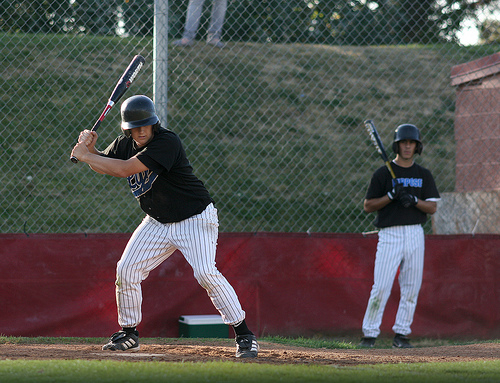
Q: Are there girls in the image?
A: No, there are no girls.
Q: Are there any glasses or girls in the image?
A: No, there are no girls or glasses.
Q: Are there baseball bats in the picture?
A: Yes, there is a baseball bat.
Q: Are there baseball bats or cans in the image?
A: Yes, there is a baseball bat.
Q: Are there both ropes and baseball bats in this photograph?
A: No, there is a baseball bat but no ropes.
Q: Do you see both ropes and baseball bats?
A: No, there is a baseball bat but no ropes.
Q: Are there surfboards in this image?
A: No, there are no surfboards.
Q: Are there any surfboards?
A: No, there are no surfboards.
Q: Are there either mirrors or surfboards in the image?
A: No, there are no surfboards or mirrors.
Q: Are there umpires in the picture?
A: No, there are no umpires.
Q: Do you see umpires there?
A: No, there are no umpires.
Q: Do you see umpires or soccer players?
A: No, there are no umpires or soccer players.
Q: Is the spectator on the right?
A: Yes, the spectator is on the right of the image.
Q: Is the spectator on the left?
A: No, the spectator is on the right of the image.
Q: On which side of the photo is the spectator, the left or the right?
A: The spectator is on the right of the image.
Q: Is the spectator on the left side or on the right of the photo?
A: The spectator is on the right of the image.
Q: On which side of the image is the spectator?
A: The spectator is on the right of the image.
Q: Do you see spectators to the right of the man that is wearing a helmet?
A: Yes, there is a spectator to the right of the man.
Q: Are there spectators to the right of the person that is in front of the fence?
A: Yes, there is a spectator to the right of the man.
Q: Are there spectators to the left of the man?
A: No, the spectator is to the right of the man.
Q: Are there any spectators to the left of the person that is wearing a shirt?
A: No, the spectator is to the right of the man.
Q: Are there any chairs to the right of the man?
A: No, there is a spectator to the right of the man.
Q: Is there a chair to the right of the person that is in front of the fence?
A: No, there is a spectator to the right of the man.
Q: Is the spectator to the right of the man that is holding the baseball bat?
A: Yes, the spectator is to the right of the man.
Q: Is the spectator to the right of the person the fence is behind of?
A: Yes, the spectator is to the right of the man.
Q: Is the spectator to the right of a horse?
A: No, the spectator is to the right of the man.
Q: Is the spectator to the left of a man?
A: No, the spectator is to the right of a man.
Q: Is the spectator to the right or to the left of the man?
A: The spectator is to the right of the man.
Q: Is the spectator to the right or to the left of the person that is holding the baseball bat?
A: The spectator is to the right of the man.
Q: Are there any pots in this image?
A: No, there are no pots.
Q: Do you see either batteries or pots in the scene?
A: No, there are no pots or batteries.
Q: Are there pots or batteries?
A: No, there are no pots or batteries.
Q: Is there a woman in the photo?
A: No, there are no women.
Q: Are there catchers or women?
A: No, there are no women or catchers.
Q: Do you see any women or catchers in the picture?
A: No, there are no women or catchers.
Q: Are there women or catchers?
A: No, there are no women or catchers.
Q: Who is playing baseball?
A: The man is playing baseball.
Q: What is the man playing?
A: The man is playing baseball.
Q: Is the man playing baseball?
A: Yes, the man is playing baseball.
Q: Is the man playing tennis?
A: No, the man is playing baseball.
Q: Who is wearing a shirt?
A: The man is wearing a shirt.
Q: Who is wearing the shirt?
A: The man is wearing a shirt.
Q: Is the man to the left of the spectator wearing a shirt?
A: Yes, the man is wearing a shirt.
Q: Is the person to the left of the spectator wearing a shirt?
A: Yes, the man is wearing a shirt.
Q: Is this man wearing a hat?
A: No, the man is wearing a shirt.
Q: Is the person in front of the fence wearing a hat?
A: No, the man is wearing a shirt.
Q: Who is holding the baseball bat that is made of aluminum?
A: The man is holding the baseball bat.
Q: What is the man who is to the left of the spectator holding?
A: The man is holding the baseball bat.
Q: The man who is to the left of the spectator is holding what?
A: The man is holding the baseball bat.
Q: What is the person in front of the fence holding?
A: The man is holding the baseball bat.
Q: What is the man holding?
A: The man is holding the baseball bat.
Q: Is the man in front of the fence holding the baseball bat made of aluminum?
A: Yes, the man is holding the baseball bat.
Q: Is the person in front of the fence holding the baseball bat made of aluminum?
A: Yes, the man is holding the baseball bat.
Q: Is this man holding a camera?
A: No, the man is holding the baseball bat.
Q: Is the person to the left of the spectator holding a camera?
A: No, the man is holding the baseball bat.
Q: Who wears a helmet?
A: The man wears a helmet.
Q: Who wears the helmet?
A: The man wears a helmet.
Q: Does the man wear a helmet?
A: Yes, the man wears a helmet.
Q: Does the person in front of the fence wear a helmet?
A: Yes, the man wears a helmet.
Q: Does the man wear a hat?
A: No, the man wears a helmet.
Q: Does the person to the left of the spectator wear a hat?
A: No, the man wears a helmet.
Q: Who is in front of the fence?
A: The man is in front of the fence.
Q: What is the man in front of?
A: The man is in front of the fence.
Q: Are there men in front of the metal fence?
A: Yes, there is a man in front of the fence.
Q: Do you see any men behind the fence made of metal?
A: No, the man is in front of the fence.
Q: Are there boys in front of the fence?
A: No, there is a man in front of the fence.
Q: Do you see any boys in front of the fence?
A: No, there is a man in front of the fence.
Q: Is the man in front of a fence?
A: Yes, the man is in front of a fence.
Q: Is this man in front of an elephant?
A: No, the man is in front of a fence.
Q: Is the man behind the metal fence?
A: No, the man is in front of the fence.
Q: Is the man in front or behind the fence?
A: The man is in front of the fence.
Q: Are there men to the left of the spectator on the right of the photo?
A: Yes, there is a man to the left of the spectator.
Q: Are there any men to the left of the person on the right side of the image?
A: Yes, there is a man to the left of the spectator.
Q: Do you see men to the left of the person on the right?
A: Yes, there is a man to the left of the spectator.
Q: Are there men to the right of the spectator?
A: No, the man is to the left of the spectator.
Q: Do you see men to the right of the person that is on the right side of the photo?
A: No, the man is to the left of the spectator.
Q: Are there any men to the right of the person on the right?
A: No, the man is to the left of the spectator.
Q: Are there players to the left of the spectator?
A: No, there is a man to the left of the spectator.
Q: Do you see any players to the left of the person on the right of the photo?
A: No, there is a man to the left of the spectator.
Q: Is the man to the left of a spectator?
A: Yes, the man is to the left of a spectator.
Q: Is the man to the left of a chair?
A: No, the man is to the left of a spectator.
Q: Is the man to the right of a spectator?
A: No, the man is to the left of a spectator.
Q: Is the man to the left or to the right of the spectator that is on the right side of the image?
A: The man is to the left of the spectator.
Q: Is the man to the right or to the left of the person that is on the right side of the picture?
A: The man is to the left of the spectator.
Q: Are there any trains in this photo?
A: No, there are no trains.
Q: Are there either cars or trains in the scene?
A: No, there are no trains or cars.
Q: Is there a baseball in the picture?
A: Yes, there is a baseball.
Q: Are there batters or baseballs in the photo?
A: Yes, there is a baseball.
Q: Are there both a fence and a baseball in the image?
A: Yes, there are both a baseball and a fence.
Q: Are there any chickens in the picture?
A: No, there are no chickens.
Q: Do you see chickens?
A: No, there are no chickens.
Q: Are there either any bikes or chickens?
A: No, there are no chickens or bikes.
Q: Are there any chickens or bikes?
A: No, there are no chickens or bikes.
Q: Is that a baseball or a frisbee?
A: That is a baseball.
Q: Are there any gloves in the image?
A: Yes, there are gloves.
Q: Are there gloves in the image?
A: Yes, there are gloves.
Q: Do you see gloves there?
A: Yes, there are gloves.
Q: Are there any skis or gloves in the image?
A: Yes, there are gloves.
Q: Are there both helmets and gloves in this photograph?
A: Yes, there are both gloves and a helmet.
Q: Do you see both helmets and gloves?
A: Yes, there are both gloves and a helmet.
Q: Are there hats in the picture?
A: No, there are no hats.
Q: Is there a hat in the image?
A: No, there are no hats.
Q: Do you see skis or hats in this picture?
A: No, there are no hats or skis.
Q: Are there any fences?
A: Yes, there is a fence.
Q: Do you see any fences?
A: Yes, there is a fence.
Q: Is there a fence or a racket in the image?
A: Yes, there is a fence.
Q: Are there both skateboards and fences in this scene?
A: No, there is a fence but no skateboards.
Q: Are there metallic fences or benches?
A: Yes, there is a metal fence.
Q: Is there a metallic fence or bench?
A: Yes, there is a metal fence.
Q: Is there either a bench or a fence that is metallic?
A: Yes, the fence is metallic.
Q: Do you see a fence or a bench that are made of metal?
A: Yes, the fence is made of metal.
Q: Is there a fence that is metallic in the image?
A: Yes, there is a metal fence.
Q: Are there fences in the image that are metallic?
A: Yes, there is a fence that is metallic.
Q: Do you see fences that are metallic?
A: Yes, there is a fence that is metallic.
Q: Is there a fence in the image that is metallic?
A: Yes, there is a fence that is metallic.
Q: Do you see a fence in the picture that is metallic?
A: Yes, there is a fence that is metallic.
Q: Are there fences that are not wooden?
A: Yes, there is a metallic fence.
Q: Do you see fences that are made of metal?
A: Yes, there is a fence that is made of metal.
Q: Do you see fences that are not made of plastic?
A: Yes, there is a fence that is made of metal.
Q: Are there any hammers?
A: No, there are no hammers.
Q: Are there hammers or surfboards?
A: No, there are no hammers or surfboards.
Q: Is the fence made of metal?
A: Yes, the fence is made of metal.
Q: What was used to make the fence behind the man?
A: The fence is made of metal.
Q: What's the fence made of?
A: The fence is made of metal.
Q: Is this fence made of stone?
A: No, the fence is made of metal.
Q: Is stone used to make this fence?
A: No, the fence is made of metal.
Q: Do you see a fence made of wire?
A: No, there is a fence but it is made of metal.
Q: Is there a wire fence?
A: No, there is a fence but it is made of metal.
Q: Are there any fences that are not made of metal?
A: No, there is a fence but it is made of metal.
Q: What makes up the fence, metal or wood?
A: The fence is made of metal.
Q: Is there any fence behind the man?
A: Yes, there is a fence behind the man.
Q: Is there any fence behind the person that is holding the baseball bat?
A: Yes, there is a fence behind the man.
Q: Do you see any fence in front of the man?
A: No, the fence is behind the man.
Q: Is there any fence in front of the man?
A: No, the fence is behind the man.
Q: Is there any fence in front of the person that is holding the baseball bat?
A: No, the fence is behind the man.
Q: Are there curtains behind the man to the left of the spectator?
A: No, there is a fence behind the man.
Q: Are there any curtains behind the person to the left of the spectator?
A: No, there is a fence behind the man.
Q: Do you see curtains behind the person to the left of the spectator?
A: No, there is a fence behind the man.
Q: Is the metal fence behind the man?
A: Yes, the fence is behind the man.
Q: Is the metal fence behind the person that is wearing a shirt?
A: Yes, the fence is behind the man.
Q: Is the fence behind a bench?
A: No, the fence is behind the man.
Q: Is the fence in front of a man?
A: No, the fence is behind a man.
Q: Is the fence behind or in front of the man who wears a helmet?
A: The fence is behind the man.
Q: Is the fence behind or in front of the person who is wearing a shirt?
A: The fence is behind the man.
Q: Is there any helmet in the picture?
A: Yes, there is a helmet.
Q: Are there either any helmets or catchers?
A: Yes, there is a helmet.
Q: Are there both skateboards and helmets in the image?
A: No, there is a helmet but no skateboards.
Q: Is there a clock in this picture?
A: No, there are no clocks.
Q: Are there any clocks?
A: No, there are no clocks.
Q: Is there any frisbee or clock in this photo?
A: No, there are no clocks or frisbees.